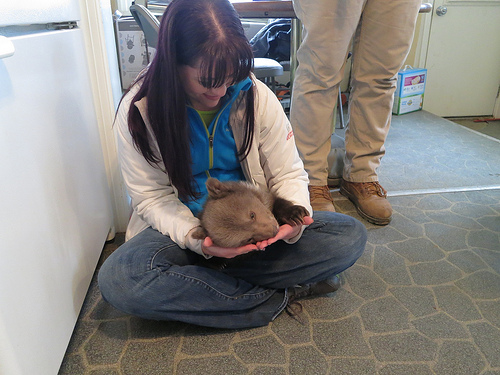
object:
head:
[190, 176, 279, 249]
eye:
[250, 212, 257, 220]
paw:
[254, 208, 315, 251]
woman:
[94, 0, 367, 332]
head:
[156, 0, 252, 109]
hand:
[200, 235, 258, 259]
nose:
[210, 84, 227, 97]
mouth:
[203, 92, 220, 100]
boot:
[338, 176, 393, 226]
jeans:
[96, 209, 368, 330]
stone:
[482, 171, 495, 180]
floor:
[398, 112, 498, 221]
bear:
[188, 175, 311, 249]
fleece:
[217, 190, 254, 212]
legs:
[96, 216, 290, 330]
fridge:
[1, 0, 130, 375]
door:
[0, 32, 118, 375]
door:
[420, 0, 499, 119]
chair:
[127, 3, 285, 100]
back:
[128, 4, 163, 48]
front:
[251, 56, 284, 78]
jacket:
[112, 62, 314, 261]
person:
[287, 0, 422, 226]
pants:
[288, 0, 421, 188]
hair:
[110, 0, 256, 207]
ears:
[205, 177, 228, 198]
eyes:
[246, 237, 253, 244]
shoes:
[306, 185, 336, 212]